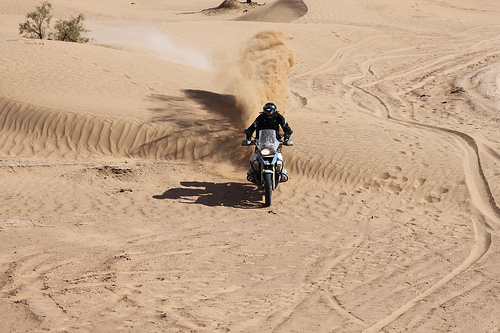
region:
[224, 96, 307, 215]
motorbike on desert sand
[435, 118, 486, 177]
tire tracks in sand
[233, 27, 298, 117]
sand kicked up behind biker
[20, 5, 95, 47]
vegetation behind sand dune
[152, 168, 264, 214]
shadow of bike on sand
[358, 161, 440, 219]
foot prints on sand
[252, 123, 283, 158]
windshield on front of bike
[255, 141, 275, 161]
light on front of bike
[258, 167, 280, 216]
front tire on bike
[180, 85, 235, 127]
shadow of flying sand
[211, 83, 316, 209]
a motorcyclist riding a dirtbike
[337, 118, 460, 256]
foot prints in the sand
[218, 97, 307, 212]
a rider wearing a black helmet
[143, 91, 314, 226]
a motorcyclist and his shadow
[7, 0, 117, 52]
trees growing in the sand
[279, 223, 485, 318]
tire tracks in the sand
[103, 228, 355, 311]
sand in the desert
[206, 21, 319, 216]
a cloud of sand behind a motorcyclist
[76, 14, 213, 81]
floating white smoke above the sand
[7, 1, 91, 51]
olive green trees in the sand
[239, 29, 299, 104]
smoky and sandy desert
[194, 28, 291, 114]
smoky and sandy desert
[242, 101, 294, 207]
a motorcycle rider riding in the desert sand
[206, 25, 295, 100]
sand is being kicked up by the motorcycle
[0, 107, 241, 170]
the desert winds shape the sand landscape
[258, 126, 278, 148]
the motorcycle windshield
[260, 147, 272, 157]
the motorcycles headlight is on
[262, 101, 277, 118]
the motorcycle helmet is black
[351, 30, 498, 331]
tracks formed in the sand by the motorcycle wheel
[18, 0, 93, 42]
a green shrub growing in the desert sand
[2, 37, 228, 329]
sand dunes formed in the sand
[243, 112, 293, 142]
a black and white motorcycle jacket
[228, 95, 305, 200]
A man riding a dirt bike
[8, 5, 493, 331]
a desert landscape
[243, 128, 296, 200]
A dirt bike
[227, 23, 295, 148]
A cloud of dust and sand from the dirt bike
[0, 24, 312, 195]
a small sand dune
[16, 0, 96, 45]
A small bush in the landscape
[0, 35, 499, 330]
Tire tracks in the sand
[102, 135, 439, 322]
footprints in the sand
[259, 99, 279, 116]
a black helmet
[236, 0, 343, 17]
A sand dune